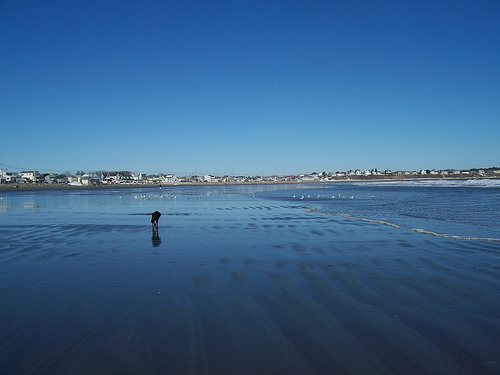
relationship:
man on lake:
[146, 206, 168, 249] [65, 202, 469, 362]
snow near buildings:
[132, 179, 189, 183] [61, 170, 237, 190]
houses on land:
[338, 162, 485, 181] [345, 175, 481, 186]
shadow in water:
[236, 210, 372, 236] [282, 191, 478, 254]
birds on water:
[287, 185, 365, 207] [282, 191, 478, 254]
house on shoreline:
[16, 168, 57, 191] [7, 180, 198, 189]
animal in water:
[180, 198, 214, 212] [282, 191, 478, 254]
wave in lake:
[421, 177, 498, 203] [0, 186, 470, 362]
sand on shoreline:
[111, 181, 328, 186] [7, 180, 198, 189]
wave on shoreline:
[421, 177, 498, 203] [7, 180, 198, 189]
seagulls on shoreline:
[131, 186, 282, 205] [7, 180, 198, 189]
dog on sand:
[13, 182, 44, 196] [111, 181, 328, 186]